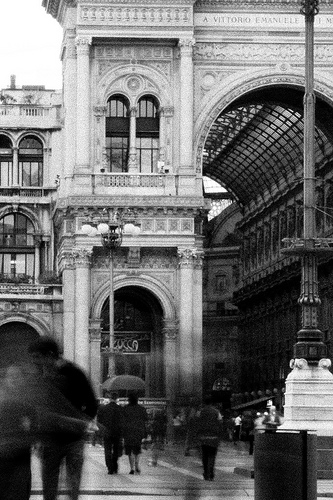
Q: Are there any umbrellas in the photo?
A: Yes, there is an umbrella.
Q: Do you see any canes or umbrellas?
A: Yes, there is an umbrella.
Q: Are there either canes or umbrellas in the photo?
A: Yes, there is an umbrella.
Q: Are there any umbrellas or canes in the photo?
A: Yes, there is an umbrella.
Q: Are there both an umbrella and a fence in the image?
A: No, there is an umbrella but no fences.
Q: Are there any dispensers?
A: No, there are no dispensers.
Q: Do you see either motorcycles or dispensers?
A: No, there are no dispensers or motorcycles.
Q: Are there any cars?
A: No, there are no cars.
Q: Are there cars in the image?
A: No, there are no cars.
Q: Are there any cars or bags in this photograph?
A: No, there are no cars or bags.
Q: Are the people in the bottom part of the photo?
A: Yes, the people are in the bottom of the image.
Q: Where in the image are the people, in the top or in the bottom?
A: The people are in the bottom of the image.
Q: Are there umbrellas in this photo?
A: Yes, there is an umbrella.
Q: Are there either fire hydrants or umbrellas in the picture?
A: Yes, there is an umbrella.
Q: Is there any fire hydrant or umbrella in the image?
A: Yes, there is an umbrella.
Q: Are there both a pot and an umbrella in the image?
A: No, there is an umbrella but no pots.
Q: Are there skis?
A: No, there are no skis.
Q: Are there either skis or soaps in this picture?
A: No, there are no skis or soaps.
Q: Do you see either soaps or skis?
A: No, there are no skis or soaps.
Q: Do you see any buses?
A: No, there are no buses.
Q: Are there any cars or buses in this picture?
A: No, there are no buses or cars.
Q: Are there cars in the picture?
A: No, there are no cars.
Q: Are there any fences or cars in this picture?
A: No, there are no cars or fences.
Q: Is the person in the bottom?
A: Yes, the person is in the bottom of the image.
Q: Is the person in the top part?
A: No, the person is in the bottom of the image.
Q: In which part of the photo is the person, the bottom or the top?
A: The person is in the bottom of the image.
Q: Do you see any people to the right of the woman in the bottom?
A: Yes, there is a person to the right of the woman.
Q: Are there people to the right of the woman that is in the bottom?
A: Yes, there is a person to the right of the woman.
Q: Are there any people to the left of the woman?
A: No, the person is to the right of the woman.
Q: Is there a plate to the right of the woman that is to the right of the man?
A: No, there is a person to the right of the woman.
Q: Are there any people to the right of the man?
A: Yes, there is a person to the right of the man.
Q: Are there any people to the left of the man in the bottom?
A: No, the person is to the right of the man.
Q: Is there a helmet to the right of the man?
A: No, there is a person to the right of the man.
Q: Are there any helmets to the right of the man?
A: No, there is a person to the right of the man.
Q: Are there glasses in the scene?
A: No, there are no glasses.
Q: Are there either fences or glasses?
A: No, there are no glasses or fences.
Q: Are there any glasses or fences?
A: No, there are no glasses or fences.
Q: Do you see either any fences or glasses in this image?
A: No, there are no glasses or fences.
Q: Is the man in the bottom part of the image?
A: Yes, the man is in the bottom of the image.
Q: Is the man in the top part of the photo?
A: No, the man is in the bottom of the image.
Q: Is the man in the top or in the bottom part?
A: The man is in the bottom of the image.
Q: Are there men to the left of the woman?
A: Yes, there is a man to the left of the woman.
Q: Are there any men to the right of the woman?
A: No, the man is to the left of the woman.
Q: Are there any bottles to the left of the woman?
A: No, there is a man to the left of the woman.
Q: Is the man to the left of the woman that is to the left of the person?
A: Yes, the man is to the left of the woman.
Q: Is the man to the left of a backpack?
A: No, the man is to the left of the woman.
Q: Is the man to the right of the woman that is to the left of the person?
A: No, the man is to the left of the woman.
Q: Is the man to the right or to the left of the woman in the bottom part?
A: The man is to the left of the woman.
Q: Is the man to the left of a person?
A: Yes, the man is to the left of a person.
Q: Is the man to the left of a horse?
A: No, the man is to the left of a person.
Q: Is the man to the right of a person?
A: No, the man is to the left of a person.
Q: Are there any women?
A: Yes, there is a woman.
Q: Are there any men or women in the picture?
A: Yes, there is a woman.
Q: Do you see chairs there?
A: No, there are no chairs.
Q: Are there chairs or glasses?
A: No, there are no chairs or glasses.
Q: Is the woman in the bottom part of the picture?
A: Yes, the woman is in the bottom of the image.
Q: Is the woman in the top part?
A: No, the woman is in the bottom of the image.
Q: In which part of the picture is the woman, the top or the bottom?
A: The woman is in the bottom of the image.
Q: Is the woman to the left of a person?
A: Yes, the woman is to the left of a person.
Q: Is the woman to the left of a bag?
A: No, the woman is to the left of a person.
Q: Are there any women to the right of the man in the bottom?
A: Yes, there is a woman to the right of the man.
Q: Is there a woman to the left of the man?
A: No, the woman is to the right of the man.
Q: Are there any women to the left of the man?
A: No, the woman is to the right of the man.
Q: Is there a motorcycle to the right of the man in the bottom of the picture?
A: No, there is a woman to the right of the man.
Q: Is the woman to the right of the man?
A: Yes, the woman is to the right of the man.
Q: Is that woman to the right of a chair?
A: No, the woman is to the right of the man.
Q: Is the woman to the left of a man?
A: No, the woman is to the right of a man.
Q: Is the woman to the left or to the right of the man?
A: The woman is to the right of the man.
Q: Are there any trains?
A: No, there are no trains.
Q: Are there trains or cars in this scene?
A: No, there are no trains or cars.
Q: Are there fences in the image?
A: No, there are no fences.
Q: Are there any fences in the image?
A: No, there are no fences.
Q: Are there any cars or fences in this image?
A: No, there are no fences or cars.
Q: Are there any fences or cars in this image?
A: No, there are no fences or cars.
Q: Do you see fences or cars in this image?
A: No, there are no fences or cars.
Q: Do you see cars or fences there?
A: No, there are no fences or cars.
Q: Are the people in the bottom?
A: Yes, the people are in the bottom of the image.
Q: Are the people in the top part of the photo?
A: No, the people are in the bottom of the image.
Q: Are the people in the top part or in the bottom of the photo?
A: The people are in the bottom of the image.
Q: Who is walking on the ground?
A: The people are walking on the ground.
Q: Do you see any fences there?
A: No, there are no fences.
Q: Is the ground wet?
A: Yes, the ground is wet.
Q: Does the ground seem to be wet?
A: Yes, the ground is wet.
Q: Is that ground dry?
A: No, the ground is wet.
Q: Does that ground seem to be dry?
A: No, the ground is wet.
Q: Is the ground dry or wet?
A: The ground is wet.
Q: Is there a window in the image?
A: Yes, there is a window.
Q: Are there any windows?
A: Yes, there is a window.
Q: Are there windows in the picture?
A: Yes, there is a window.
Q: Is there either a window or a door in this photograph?
A: Yes, there is a window.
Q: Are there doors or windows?
A: Yes, there is a window.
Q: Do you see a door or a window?
A: Yes, there is a window.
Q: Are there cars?
A: No, there are no cars.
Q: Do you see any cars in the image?
A: No, there are no cars.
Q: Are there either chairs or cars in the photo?
A: No, there are no cars or chairs.